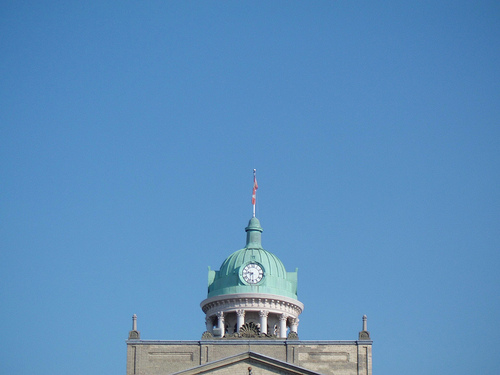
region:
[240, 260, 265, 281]
a white face clock on side of the dome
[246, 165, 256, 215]
a flag on a white pole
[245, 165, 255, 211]
a flag on top of a light blue dome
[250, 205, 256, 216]
a white flag pole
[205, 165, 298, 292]
a light blue dome on top of a building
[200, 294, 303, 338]
a white columnar building below the light blue dome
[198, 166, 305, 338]
a clock tower on top of a building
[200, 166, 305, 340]
a light blue dome with a clock on the side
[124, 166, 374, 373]
a dome clock tower on top of a historical building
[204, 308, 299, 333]
white columns below the clocks on the dome tower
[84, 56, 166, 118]
Part of the blue sky.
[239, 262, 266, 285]
A clock on the building.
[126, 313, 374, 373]
Part of the grey building.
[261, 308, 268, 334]
A white pillar.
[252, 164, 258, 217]
A tall white pole.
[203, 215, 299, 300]
The green part of the building.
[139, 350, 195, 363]
Part of the grey wall.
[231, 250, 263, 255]
Part of the green roof.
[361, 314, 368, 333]
A small grey pole.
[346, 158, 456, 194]
Part of the sky.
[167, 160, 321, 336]
the top of the building is dome shaped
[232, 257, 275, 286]
the face of the clock is white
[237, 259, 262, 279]
the numbers are roman numerals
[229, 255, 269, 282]
the numbers are black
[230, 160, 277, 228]
a flag on top the dome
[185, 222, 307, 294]
the dome is green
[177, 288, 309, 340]
the bottom of the dome is white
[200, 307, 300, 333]
white pillars around the dome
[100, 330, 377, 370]
the building is grey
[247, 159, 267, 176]
a ball on top the flag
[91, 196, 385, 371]
top of large capital building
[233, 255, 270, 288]
round clock on building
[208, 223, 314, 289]
green copper top of building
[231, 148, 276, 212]
flag pole on top of building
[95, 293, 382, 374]
stone walls of building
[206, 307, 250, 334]
white pillars on roof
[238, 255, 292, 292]
roman numerals on building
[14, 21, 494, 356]
clear blue sky above building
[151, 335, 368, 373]
stained concrete on building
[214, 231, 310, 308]
copper roof turned green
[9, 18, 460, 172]
sky is clear and blue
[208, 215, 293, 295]
top of building is green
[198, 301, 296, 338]
base of top is white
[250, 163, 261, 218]
flag on top of peak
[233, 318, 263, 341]
emblem is design on building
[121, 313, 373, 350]
two pillars on top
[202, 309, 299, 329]
columns in the front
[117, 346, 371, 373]
top part of building in concrete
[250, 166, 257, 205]
flag is red and white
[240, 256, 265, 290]
clock in roman numbers